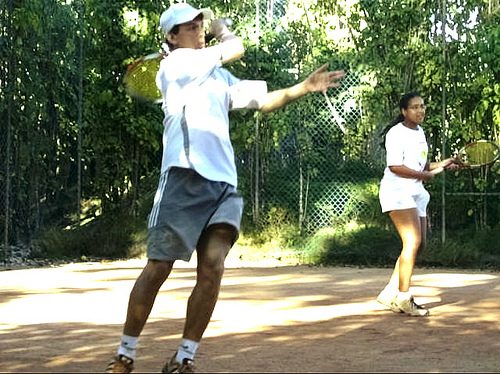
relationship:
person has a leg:
[105, 3, 348, 373] [173, 225, 237, 363]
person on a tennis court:
[105, 3, 348, 373] [0, 2, 497, 373]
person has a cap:
[105, 3, 348, 373] [158, 3, 212, 38]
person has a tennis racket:
[105, 3, 348, 373] [122, 20, 234, 104]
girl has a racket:
[379, 90, 472, 316] [420, 138, 499, 180]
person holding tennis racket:
[105, 3, 348, 373] [122, 20, 234, 104]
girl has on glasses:
[379, 90, 472, 316] [404, 106, 429, 112]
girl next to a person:
[379, 90, 472, 316] [105, 3, 348, 373]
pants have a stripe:
[147, 166, 244, 262] [147, 167, 172, 227]